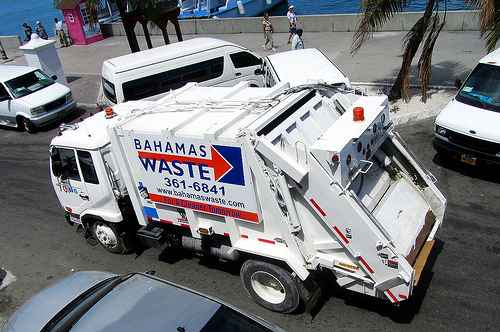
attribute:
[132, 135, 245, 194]
logo — blue, company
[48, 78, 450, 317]
truck — large, daytime, white, waste, garbage, numbered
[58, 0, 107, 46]
kiosk — small, pink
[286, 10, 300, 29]
shirt — white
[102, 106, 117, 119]
signal — small, orange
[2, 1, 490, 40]
water — calm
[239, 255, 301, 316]
wheel — white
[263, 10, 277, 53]
person — walking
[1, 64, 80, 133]
van — parked, white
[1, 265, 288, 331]
car — silver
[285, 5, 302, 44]
man — walking